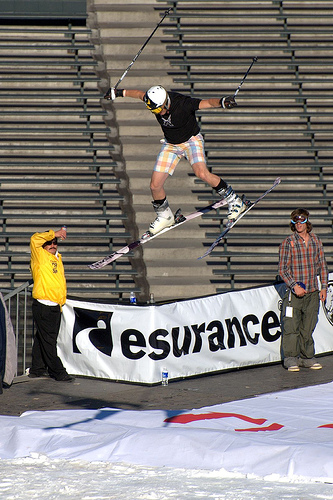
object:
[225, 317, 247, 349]
letter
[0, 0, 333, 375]
empty bleachers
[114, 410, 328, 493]
tarp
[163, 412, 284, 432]
red stripe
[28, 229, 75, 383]
man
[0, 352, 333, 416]
cement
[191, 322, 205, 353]
letter r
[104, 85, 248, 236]
poles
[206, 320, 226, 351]
black letter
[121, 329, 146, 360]
letter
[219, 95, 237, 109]
glove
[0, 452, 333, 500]
snow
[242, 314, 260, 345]
black letter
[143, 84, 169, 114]
helmet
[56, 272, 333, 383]
banner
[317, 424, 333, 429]
stripe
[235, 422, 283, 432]
stripe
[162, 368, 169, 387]
bottle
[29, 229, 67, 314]
jacket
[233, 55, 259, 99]
ski pole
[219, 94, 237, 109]
hand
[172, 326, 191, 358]
letter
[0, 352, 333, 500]
ground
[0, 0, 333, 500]
event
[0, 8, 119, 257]
stands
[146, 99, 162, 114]
yellow goggles